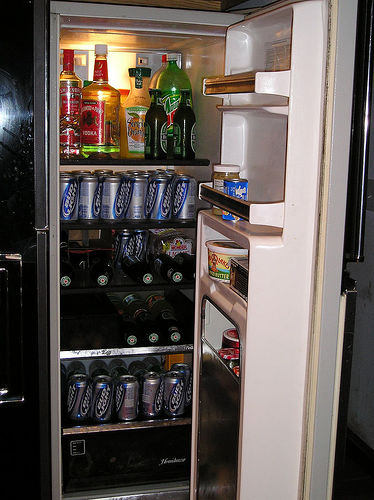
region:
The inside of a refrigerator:
[32, 4, 284, 489]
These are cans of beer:
[68, 367, 192, 423]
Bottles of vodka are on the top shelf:
[60, 43, 119, 158]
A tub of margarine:
[203, 235, 246, 285]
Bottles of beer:
[145, 87, 196, 157]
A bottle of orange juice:
[116, 64, 153, 159]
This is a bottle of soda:
[156, 51, 192, 109]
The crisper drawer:
[59, 414, 191, 490]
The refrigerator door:
[194, 2, 364, 493]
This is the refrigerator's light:
[87, 45, 140, 89]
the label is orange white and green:
[124, 104, 144, 153]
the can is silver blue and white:
[163, 367, 189, 417]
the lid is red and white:
[213, 341, 248, 370]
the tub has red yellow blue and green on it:
[202, 236, 251, 293]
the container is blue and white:
[221, 175, 260, 215]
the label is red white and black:
[79, 94, 103, 147]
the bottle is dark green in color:
[143, 83, 171, 162]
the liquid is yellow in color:
[107, 98, 122, 145]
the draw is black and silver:
[59, 416, 203, 484]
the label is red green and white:
[161, 94, 182, 136]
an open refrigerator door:
[48, 4, 356, 492]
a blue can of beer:
[63, 373, 91, 423]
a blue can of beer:
[91, 372, 110, 420]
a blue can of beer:
[112, 371, 137, 421]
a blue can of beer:
[142, 371, 161, 416]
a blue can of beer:
[163, 369, 182, 417]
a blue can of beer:
[170, 362, 191, 402]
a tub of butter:
[198, 237, 243, 279]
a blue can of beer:
[58, 175, 75, 217]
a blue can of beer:
[103, 176, 123, 219]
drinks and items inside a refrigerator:
[67, 32, 283, 434]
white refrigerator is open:
[190, 1, 362, 494]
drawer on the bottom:
[52, 421, 193, 491]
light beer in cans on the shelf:
[63, 361, 192, 421]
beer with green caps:
[65, 266, 184, 347]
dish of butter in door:
[200, 235, 239, 292]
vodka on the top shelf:
[71, 43, 115, 157]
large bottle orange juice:
[117, 64, 148, 163]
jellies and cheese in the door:
[194, 315, 246, 395]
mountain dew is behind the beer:
[148, 47, 195, 154]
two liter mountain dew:
[160, 53, 199, 164]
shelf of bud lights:
[57, 364, 196, 416]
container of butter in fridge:
[199, 227, 246, 286]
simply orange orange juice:
[115, 67, 159, 165]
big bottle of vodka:
[76, 38, 132, 161]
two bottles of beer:
[140, 84, 202, 159]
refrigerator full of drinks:
[28, 2, 347, 498]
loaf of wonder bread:
[143, 223, 201, 266]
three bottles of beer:
[99, 292, 189, 352]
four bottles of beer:
[51, 239, 190, 294]